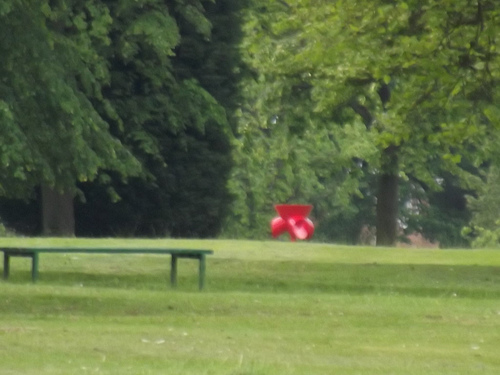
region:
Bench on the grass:
[0, 243, 216, 294]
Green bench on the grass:
[0, 242, 213, 292]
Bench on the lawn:
[0, 235, 220, 292]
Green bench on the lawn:
[0, 241, 218, 294]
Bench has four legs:
[0, 238, 215, 290]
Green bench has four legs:
[0, 236, 212, 296]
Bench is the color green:
[0, 236, 215, 291]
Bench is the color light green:
[0, 236, 216, 292]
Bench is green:
[0, 240, 217, 293]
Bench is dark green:
[1, 242, 214, 294]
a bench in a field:
[1, 243, 211, 286]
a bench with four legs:
[0, 244, 212, 286]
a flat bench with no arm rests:
[0, 243, 217, 287]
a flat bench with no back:
[2, 244, 214, 287]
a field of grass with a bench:
[0, 237, 499, 373]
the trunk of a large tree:
[42, 137, 77, 238]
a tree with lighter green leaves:
[269, 1, 496, 250]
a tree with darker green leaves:
[1, 2, 233, 237]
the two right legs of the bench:
[169, 252, 206, 289]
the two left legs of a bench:
[2, 248, 40, 279]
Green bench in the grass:
[1, 231, 211, 301]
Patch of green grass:
[17, 337, 64, 369]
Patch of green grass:
[60, 329, 113, 365]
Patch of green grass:
[105, 328, 158, 372]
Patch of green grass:
[156, 328, 201, 368]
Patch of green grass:
[213, 327, 255, 373]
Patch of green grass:
[260, 331, 307, 369]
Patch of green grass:
[308, 334, 343, 369]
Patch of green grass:
[341, 329, 378, 374]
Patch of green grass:
[385, 327, 412, 370]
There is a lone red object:
[265, 194, 335, 246]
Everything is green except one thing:
[1, 20, 484, 368]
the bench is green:
[1, 245, 210, 292]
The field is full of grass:
[58, 262, 442, 370]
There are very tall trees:
[1, 8, 478, 291]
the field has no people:
[7, 45, 490, 370]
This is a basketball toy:
[267, 190, 318, 246]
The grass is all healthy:
[0, 245, 465, 370]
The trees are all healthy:
[10, 17, 460, 202]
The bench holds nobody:
[9, 242, 216, 311]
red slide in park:
[262, 198, 318, 250]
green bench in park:
[2, 240, 221, 295]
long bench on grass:
[0, 239, 220, 301]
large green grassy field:
[3, 220, 497, 371]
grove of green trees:
[2, 0, 498, 255]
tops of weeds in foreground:
[174, 350, 309, 373]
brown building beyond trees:
[337, 168, 479, 255]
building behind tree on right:
[287, 152, 464, 255]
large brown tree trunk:
[28, 140, 90, 241]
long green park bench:
[0, 240, 222, 301]